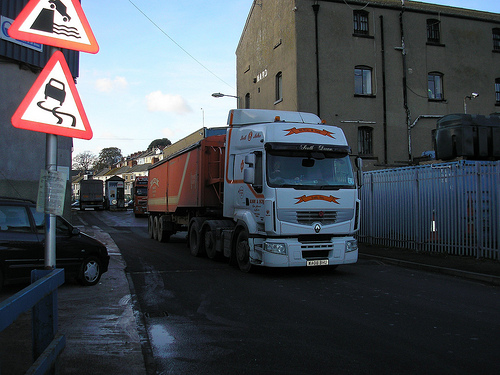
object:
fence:
[355, 160, 500, 266]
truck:
[145, 107, 366, 274]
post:
[44, 132, 59, 267]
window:
[354, 64, 376, 100]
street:
[23, 207, 500, 375]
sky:
[72, 2, 254, 164]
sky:
[418, 0, 498, 15]